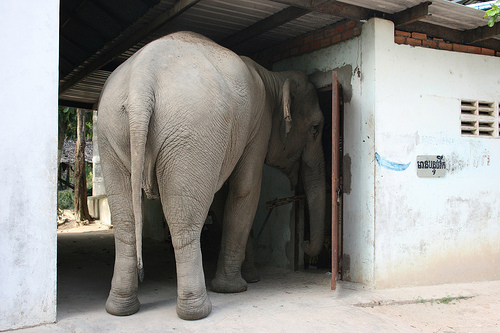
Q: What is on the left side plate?
A: Lunch meats, cheeses, bread.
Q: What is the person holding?
A: A sugar bowl.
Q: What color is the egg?
A: Brown.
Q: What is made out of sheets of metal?
A: The roof.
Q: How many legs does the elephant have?
A: Four.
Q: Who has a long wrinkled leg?
A: The elephant.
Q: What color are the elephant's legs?
A: Grey.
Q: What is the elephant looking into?
A: The house.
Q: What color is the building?
A: White.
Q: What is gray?
A: The elephant.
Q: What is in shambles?
A: The building.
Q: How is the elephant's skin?
A: It's wrinkly.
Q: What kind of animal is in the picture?
A: Elephant.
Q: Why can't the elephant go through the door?
A: It is too small.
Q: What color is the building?
A: White.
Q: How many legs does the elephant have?
A: Four.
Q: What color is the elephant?
A: Gray.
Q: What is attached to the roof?
A: Tin.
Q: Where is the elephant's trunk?
A: In the doorway.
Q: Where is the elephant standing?
A: Under the roof.